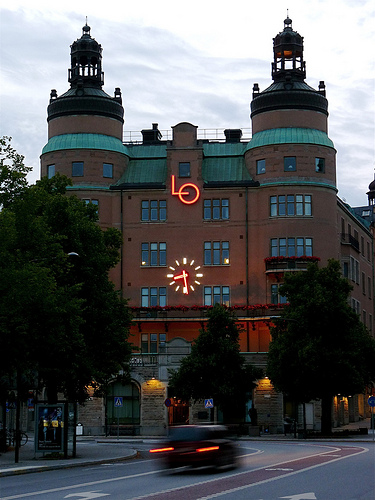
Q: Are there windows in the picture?
A: Yes, there is a window.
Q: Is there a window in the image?
A: Yes, there is a window.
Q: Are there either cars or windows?
A: Yes, there is a window.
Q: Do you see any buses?
A: No, there are no buses.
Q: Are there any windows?
A: Yes, there is a window.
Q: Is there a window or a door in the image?
A: Yes, there is a window.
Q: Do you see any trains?
A: No, there are no trains.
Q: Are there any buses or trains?
A: No, there are no trains or buses.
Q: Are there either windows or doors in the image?
A: Yes, there is a window.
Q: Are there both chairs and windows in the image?
A: No, there is a window but no chairs.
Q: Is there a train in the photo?
A: No, there are no trains.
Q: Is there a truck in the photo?
A: No, there are no trucks.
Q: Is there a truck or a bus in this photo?
A: No, there are no trucks or buses.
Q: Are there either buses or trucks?
A: No, there are no trucks or buses.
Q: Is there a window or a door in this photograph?
A: Yes, there is a window.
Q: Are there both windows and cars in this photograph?
A: Yes, there are both a window and a car.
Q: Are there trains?
A: No, there are no trains.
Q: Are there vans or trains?
A: No, there are no trains or vans.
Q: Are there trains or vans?
A: No, there are no trains or vans.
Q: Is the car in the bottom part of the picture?
A: Yes, the car is in the bottom of the image.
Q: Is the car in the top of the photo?
A: No, the car is in the bottom of the image.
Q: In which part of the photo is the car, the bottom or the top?
A: The car is in the bottom of the image.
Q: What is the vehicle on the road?
A: The vehicle is a car.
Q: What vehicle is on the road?
A: The vehicle is a car.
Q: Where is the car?
A: The car is on the road.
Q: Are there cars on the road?
A: Yes, there is a car on the road.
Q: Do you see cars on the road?
A: Yes, there is a car on the road.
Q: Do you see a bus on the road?
A: No, there is a car on the road.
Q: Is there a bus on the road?
A: No, there is a car on the road.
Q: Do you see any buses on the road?
A: No, there is a car on the road.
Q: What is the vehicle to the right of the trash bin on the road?
A: The vehicle is a car.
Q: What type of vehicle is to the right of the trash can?
A: The vehicle is a car.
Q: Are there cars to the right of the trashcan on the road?
A: Yes, there is a car to the right of the garbage bin.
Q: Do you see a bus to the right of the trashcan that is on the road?
A: No, there is a car to the right of the trash can.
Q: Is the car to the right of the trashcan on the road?
A: Yes, the car is to the right of the garbage bin.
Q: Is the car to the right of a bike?
A: No, the car is to the right of the garbage bin.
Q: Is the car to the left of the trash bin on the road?
A: No, the car is to the right of the trashcan.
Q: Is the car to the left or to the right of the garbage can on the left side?
A: The car is to the right of the garbage can.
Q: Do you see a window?
A: Yes, there is a window.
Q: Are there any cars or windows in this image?
A: Yes, there is a window.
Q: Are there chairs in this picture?
A: No, there are no chairs.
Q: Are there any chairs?
A: No, there are no chairs.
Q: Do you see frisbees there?
A: No, there are no frisbees.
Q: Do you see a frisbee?
A: No, there are no frisbees.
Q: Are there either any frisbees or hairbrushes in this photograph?
A: No, there are no frisbees or hairbrushes.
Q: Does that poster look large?
A: Yes, the poster is large.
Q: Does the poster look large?
A: Yes, the poster is large.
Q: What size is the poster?
A: The poster is large.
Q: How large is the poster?
A: The poster is large.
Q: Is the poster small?
A: No, the poster is large.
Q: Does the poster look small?
A: No, the poster is large.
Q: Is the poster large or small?
A: The poster is large.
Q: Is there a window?
A: Yes, there is a window.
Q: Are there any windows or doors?
A: Yes, there is a window.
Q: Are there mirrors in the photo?
A: No, there are no mirrors.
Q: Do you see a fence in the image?
A: No, there are no fences.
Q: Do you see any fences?
A: No, there are no fences.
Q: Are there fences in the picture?
A: No, there are no fences.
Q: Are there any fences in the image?
A: No, there are no fences.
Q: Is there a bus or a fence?
A: No, there are no fences or buses.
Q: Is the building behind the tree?
A: Yes, the building is behind the tree.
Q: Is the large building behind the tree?
A: Yes, the building is behind the tree.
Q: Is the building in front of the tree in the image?
A: No, the building is behind the tree.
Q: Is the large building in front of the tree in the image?
A: No, the building is behind the tree.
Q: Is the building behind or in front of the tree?
A: The building is behind the tree.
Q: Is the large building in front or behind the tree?
A: The building is behind the tree.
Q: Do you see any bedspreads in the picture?
A: No, there are no bedspreads.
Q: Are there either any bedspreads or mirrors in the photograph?
A: No, there are no bedspreads or mirrors.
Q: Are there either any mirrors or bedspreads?
A: No, there are no bedspreads or mirrors.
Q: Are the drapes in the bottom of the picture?
A: Yes, the drapes are in the bottom of the image.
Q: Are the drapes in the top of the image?
A: No, the drapes are in the bottom of the image.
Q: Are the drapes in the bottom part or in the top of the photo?
A: The drapes are in the bottom of the image.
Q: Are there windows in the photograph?
A: Yes, there is a window.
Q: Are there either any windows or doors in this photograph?
A: Yes, there is a window.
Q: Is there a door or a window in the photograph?
A: Yes, there is a window.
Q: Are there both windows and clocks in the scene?
A: Yes, there are both a window and a clock.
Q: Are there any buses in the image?
A: No, there are no buses.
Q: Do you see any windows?
A: Yes, there is a window.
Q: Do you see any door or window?
A: Yes, there is a window.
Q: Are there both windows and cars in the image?
A: Yes, there are both a window and a car.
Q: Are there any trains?
A: No, there are no trains.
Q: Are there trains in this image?
A: No, there are no trains.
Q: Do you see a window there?
A: Yes, there is a window.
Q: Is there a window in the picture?
A: Yes, there is a window.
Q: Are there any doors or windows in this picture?
A: Yes, there is a window.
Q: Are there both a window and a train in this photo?
A: No, there is a window but no trains.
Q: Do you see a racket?
A: No, there are no rackets.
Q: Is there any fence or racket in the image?
A: No, there are no rackets or fences.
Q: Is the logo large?
A: Yes, the logo is large.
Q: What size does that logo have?
A: The logo has large size.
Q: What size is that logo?
A: The logo is large.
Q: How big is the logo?
A: The logo is large.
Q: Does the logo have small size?
A: No, the logo is large.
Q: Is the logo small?
A: No, the logo is large.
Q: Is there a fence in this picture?
A: No, there are no fences.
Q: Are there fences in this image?
A: No, there are no fences.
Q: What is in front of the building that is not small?
A: The tree is in front of the building.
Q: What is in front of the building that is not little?
A: The tree is in front of the building.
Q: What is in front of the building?
A: The tree is in front of the building.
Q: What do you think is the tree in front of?
A: The tree is in front of the building.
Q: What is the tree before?
A: The tree is in front of the building.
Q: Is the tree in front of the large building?
A: Yes, the tree is in front of the building.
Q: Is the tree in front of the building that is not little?
A: Yes, the tree is in front of the building.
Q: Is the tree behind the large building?
A: No, the tree is in front of the building.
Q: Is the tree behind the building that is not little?
A: No, the tree is in front of the building.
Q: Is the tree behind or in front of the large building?
A: The tree is in front of the building.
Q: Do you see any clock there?
A: Yes, there is a clock.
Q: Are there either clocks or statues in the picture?
A: Yes, there is a clock.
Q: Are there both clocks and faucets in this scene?
A: No, there is a clock but no faucets.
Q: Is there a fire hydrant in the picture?
A: No, there are no fire hydrants.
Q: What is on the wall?
A: The clock is on the wall.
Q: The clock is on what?
A: The clock is on the wall.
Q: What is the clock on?
A: The clock is on the wall.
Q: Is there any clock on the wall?
A: Yes, there is a clock on the wall.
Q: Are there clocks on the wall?
A: Yes, there is a clock on the wall.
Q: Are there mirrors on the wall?
A: No, there is a clock on the wall.